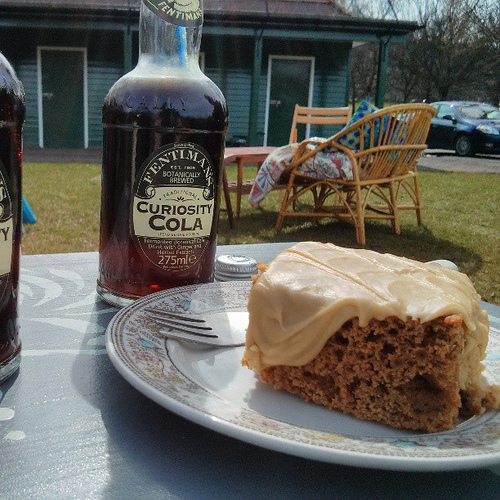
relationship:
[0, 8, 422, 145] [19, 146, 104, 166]
building with porch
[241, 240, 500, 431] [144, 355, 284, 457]
cake on plate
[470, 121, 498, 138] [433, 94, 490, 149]
headlight on car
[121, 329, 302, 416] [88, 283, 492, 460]
design around edge of plate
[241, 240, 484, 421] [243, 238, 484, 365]
cake with icing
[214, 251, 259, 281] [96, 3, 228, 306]
cap for bottle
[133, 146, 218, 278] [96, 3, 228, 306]
label on front of bottle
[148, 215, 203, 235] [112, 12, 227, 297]
cola on front of bottle front